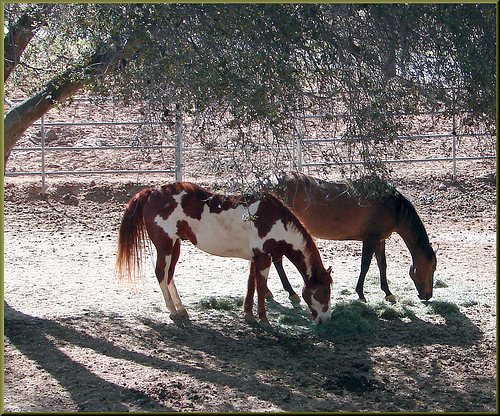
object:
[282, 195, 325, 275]
mane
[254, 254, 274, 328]
legs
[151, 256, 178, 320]
legs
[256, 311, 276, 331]
hoof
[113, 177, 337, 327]
horse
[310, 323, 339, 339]
hay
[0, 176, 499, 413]
prairie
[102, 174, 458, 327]
horse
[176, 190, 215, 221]
spots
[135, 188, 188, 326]
thigh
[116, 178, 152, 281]
tail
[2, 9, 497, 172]
tree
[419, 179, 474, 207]
dirt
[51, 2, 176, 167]
tree branch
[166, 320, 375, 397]
horse shadow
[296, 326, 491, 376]
grass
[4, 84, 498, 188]
fence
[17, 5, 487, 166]
leaves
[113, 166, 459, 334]
horse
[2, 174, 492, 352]
ground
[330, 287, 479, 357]
horse shadow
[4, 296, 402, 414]
tree shadow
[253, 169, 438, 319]
horse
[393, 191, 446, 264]
mane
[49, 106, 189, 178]
enclosure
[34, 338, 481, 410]
shadow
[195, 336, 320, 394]
ground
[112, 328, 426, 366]
grass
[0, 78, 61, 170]
tree trunk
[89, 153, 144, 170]
dirt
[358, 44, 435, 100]
branch